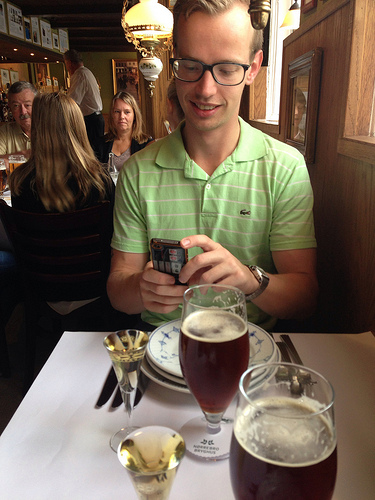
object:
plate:
[146, 309, 280, 378]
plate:
[146, 311, 277, 386]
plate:
[137, 319, 283, 396]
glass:
[100, 324, 149, 455]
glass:
[178, 284, 250, 460]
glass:
[229, 360, 337, 500]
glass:
[109, 421, 181, 500]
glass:
[0, 155, 30, 199]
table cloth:
[2, 329, 93, 495]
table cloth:
[302, 334, 372, 368]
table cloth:
[339, 335, 369, 495]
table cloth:
[184, 464, 227, 497]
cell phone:
[149, 238, 189, 287]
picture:
[280, 48, 323, 166]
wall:
[272, 1, 373, 334]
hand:
[138, 258, 195, 315]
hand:
[175, 232, 251, 298]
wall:
[140, 1, 373, 331]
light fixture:
[119, 0, 174, 97]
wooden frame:
[278, 45, 325, 166]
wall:
[282, 0, 373, 332]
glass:
[172, 276, 258, 463]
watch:
[246, 263, 270, 301]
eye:
[182, 63, 199, 73]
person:
[106, 0, 319, 350]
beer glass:
[172, 283, 249, 464]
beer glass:
[229, 362, 337, 499]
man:
[107, 1, 318, 335]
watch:
[247, 258, 271, 300]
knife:
[95, 360, 122, 409]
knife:
[109, 386, 122, 409]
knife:
[131, 372, 149, 407]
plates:
[138, 315, 286, 396]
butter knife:
[95, 364, 125, 409]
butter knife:
[111, 335, 138, 410]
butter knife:
[133, 339, 150, 409]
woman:
[6, 88, 141, 331]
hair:
[6, 89, 113, 214]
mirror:
[286, 70, 309, 145]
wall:
[317, 11, 356, 171]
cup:
[103, 330, 150, 453]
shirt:
[110, 115, 318, 332]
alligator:
[240, 208, 251, 214]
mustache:
[19, 114, 30, 119]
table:
[0, 330, 373, 499]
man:
[0, 80, 38, 162]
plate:
[144, 312, 278, 393]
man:
[64, 49, 106, 166]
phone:
[149, 237, 189, 289]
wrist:
[244, 254, 278, 311]